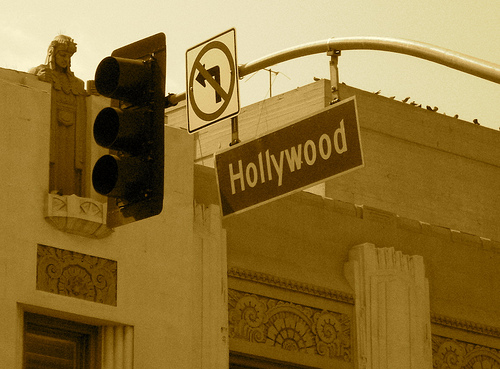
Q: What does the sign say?
A: Hollywood.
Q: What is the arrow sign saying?
A: No left turn.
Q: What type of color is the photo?
A: White and black.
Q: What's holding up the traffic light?
A: Pole.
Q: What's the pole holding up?
A: Traffic light.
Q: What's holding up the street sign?
A: Pole.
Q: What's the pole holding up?
A: Street sign.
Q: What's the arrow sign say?
A: No left turn.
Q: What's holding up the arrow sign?
A: Pole.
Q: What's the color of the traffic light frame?
A: Black.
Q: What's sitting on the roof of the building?
A: Birds.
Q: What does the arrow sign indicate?
A: No left turn.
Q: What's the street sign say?
A: Hollywood.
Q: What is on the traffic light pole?
A: Hollywood sign.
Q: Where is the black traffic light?
A: On pole.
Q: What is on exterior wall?
A: Large filligree inlet.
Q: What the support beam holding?
A: Traffic light and signs.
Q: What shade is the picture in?
A: Black and white.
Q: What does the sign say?
A: Hollywood.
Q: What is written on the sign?
A: Hollywood.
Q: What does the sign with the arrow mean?
A: No left turn.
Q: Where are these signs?
A: At an intersection.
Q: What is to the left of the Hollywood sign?
A: Traffic light.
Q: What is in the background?
A: Building.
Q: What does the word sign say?
A: Hollywood.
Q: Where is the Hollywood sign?
A: Hanging.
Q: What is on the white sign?
A: No turn sign.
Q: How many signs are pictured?
A: 2.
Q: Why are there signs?
A: For driving purposes.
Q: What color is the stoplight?
A: Black.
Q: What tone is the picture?
A: Sepia.